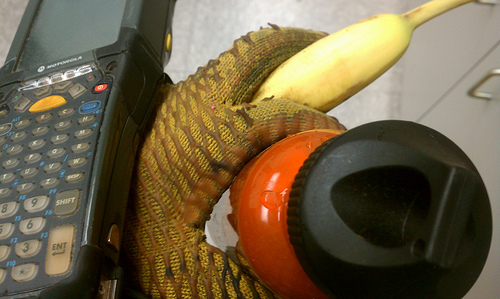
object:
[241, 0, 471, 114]
banana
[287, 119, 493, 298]
lid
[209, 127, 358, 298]
cup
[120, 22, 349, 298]
cover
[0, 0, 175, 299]
scanner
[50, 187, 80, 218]
buttons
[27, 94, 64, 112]
button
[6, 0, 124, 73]
screen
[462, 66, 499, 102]
handle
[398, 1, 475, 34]
stalk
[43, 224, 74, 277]
button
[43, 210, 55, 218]
numbers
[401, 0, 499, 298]
door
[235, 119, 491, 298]
container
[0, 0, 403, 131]
floor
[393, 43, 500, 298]
cupboard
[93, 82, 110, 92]
button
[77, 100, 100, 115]
button